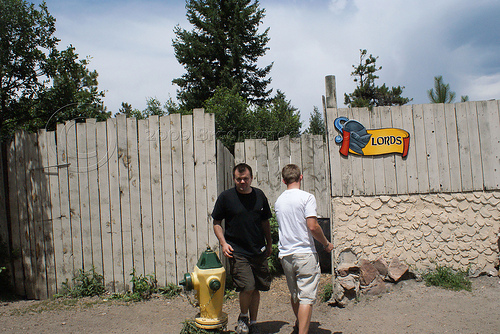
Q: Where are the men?
A: In front of the fence.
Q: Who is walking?
A: The men.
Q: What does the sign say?
A: "Lords.".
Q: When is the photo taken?
A: Daytime.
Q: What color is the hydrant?
A: Yellow and green.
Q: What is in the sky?
A: Clouds.